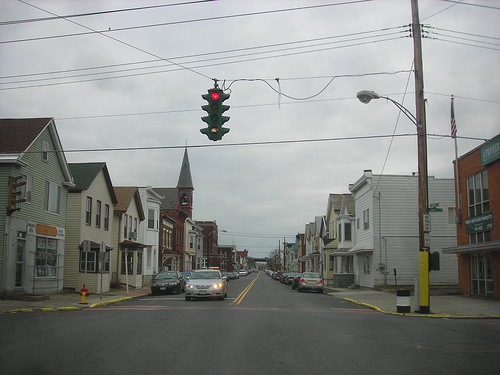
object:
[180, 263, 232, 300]
car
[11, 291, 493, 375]
road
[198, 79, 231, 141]
light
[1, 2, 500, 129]
sky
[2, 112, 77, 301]
buildings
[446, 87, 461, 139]
flag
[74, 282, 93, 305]
hydrant